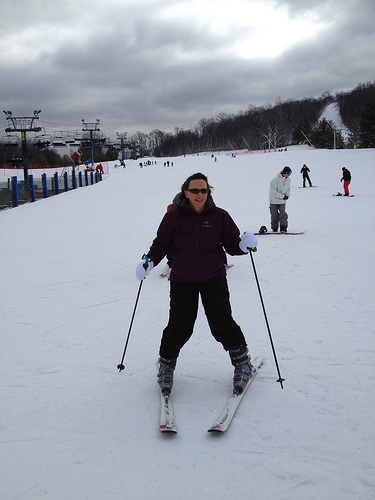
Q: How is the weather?
A: It is cloudy.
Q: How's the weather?
A: It is cloudy.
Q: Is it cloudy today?
A: Yes, it is cloudy.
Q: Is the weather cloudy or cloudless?
A: It is cloudy.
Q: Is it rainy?
A: No, it is cloudy.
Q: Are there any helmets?
A: No, there are no helmets.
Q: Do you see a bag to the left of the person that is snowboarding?
A: No, there is a skier to the left of the person.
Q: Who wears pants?
A: The skier wears pants.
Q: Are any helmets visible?
A: No, there are no helmets.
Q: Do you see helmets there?
A: No, there are no helmets.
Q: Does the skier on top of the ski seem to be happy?
A: Yes, the skier is happy.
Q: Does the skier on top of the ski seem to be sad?
A: No, the skier is happy.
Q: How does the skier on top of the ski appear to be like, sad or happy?
A: The skier is happy.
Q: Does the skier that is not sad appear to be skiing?
A: Yes, the skier is skiing.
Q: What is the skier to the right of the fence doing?
A: The skier is skiing.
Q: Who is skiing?
A: The skier is skiing.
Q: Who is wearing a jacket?
A: The skier is wearing a jacket.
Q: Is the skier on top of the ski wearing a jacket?
A: Yes, the skier is wearing a jacket.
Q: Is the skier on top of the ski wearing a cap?
A: No, the skier is wearing a jacket.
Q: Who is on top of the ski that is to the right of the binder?
A: The skier is on top of the ski.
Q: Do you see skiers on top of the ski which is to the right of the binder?
A: Yes, there is a skier on top of the ski.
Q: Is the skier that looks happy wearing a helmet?
A: No, the skier is wearing a glove.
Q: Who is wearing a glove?
A: The skier is wearing a glove.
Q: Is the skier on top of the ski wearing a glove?
A: Yes, the skier is wearing a glove.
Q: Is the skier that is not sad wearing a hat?
A: No, the skier is wearing a glove.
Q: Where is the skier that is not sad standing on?
A: The skier is standing on the snow.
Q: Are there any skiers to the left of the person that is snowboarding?
A: Yes, there is a skier to the left of the person.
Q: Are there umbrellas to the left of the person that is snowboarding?
A: No, there is a skier to the left of the person.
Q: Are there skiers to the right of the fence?
A: Yes, there is a skier to the right of the fence.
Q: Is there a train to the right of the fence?
A: No, there is a skier to the right of the fence.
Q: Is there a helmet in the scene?
A: No, there are no helmets.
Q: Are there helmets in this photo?
A: No, there are no helmets.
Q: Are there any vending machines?
A: No, there are no vending machines.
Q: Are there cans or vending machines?
A: No, there are no vending machines or cans.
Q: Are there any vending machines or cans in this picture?
A: No, there are no vending machines or cans.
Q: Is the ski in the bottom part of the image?
A: Yes, the ski is in the bottom of the image.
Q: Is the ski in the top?
A: No, the ski is in the bottom of the image.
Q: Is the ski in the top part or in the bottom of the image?
A: The ski is in the bottom of the image.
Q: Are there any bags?
A: No, there are no bags.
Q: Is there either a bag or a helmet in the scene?
A: No, there are no bags or helmets.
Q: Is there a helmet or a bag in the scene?
A: No, there are no bags or helmets.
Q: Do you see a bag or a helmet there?
A: No, there are no bags or helmets.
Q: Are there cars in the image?
A: No, there are no cars.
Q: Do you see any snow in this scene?
A: Yes, there is snow.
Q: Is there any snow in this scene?
A: Yes, there is snow.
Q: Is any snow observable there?
A: Yes, there is snow.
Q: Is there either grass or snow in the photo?
A: Yes, there is snow.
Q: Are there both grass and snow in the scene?
A: No, there is snow but no grass.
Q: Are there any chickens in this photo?
A: No, there are no chickens.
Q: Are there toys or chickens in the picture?
A: No, there are no chickens or toys.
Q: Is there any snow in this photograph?
A: Yes, there is snow.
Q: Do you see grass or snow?
A: Yes, there is snow.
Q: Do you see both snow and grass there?
A: No, there is snow but no grass.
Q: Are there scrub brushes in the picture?
A: No, there are no scrub brushes.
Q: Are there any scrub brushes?
A: No, there are no scrub brushes.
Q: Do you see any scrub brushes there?
A: No, there are no scrub brushes.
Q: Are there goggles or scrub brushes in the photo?
A: No, there are no scrub brushes or goggles.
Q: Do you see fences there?
A: Yes, there is a fence.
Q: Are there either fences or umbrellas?
A: Yes, there is a fence.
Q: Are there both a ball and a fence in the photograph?
A: No, there is a fence but no balls.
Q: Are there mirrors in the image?
A: No, there are no mirrors.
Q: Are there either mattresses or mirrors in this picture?
A: No, there are no mirrors or mattresses.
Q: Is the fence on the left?
A: Yes, the fence is on the left of the image.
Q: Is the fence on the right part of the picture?
A: No, the fence is on the left of the image.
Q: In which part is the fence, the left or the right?
A: The fence is on the left of the image.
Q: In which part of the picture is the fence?
A: The fence is on the left of the image.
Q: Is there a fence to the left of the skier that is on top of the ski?
A: Yes, there is a fence to the left of the skier.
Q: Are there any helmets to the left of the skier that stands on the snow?
A: No, there is a fence to the left of the skier.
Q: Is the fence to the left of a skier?
A: Yes, the fence is to the left of a skier.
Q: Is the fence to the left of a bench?
A: No, the fence is to the left of a skier.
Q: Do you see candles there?
A: No, there are no candles.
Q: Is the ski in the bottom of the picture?
A: Yes, the ski is in the bottom of the image.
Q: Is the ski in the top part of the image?
A: No, the ski is in the bottom of the image.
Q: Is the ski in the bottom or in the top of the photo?
A: The ski is in the bottom of the image.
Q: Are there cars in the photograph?
A: No, there are no cars.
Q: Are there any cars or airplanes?
A: No, there are no cars or airplanes.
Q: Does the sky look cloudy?
A: Yes, the sky is cloudy.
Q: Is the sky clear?
A: No, the sky is cloudy.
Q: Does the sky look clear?
A: No, the sky is cloudy.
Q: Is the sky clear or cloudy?
A: The sky is cloudy.